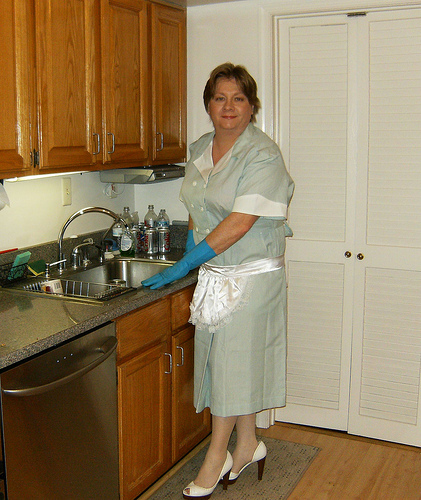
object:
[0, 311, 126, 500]
dishwasher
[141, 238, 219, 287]
glove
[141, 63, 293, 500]
woman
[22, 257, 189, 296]
sink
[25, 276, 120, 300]
drainer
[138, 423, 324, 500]
mat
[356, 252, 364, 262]
knobs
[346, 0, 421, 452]
doors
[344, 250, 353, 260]
gold knobs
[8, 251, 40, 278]
sponge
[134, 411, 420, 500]
wood flooring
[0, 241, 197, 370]
gray counter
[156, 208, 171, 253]
bottles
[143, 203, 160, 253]
bottles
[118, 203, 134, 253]
bottles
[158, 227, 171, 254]
cans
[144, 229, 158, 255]
cans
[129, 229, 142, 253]
cans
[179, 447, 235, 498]
dress shoe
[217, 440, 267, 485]
dress shoe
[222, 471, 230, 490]
heel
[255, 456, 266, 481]
heel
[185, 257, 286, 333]
apron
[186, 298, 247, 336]
lace edging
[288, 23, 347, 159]
slats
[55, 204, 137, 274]
faucet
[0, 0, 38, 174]
cabinets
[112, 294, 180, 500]
cabinets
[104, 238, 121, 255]
scrub brush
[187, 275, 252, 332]
trim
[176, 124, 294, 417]
dress